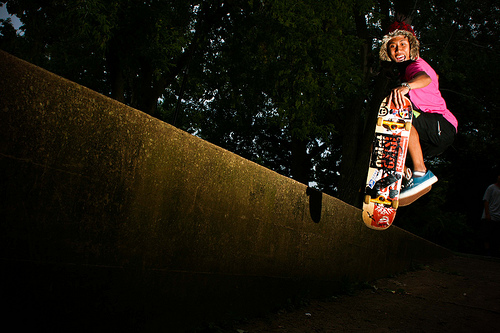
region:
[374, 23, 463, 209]
skateboarder wearing pink shirt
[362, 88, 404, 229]
decorated bottom of the skateboard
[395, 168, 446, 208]
skateboarder's blue shoes with white laces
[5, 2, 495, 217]
trees behind skateboarder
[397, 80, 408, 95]
skateboarder's wrist watch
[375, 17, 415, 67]
skateboarder's red hat with fuzzy trim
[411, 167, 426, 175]
skateboarder's white ankle sock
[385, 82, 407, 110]
skateboarder's hand gripping skateboard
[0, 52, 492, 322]
cement wall behind skateboarder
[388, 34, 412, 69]
skateboarder's smiling face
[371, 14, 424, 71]
Skateboarder is wearing a fake fur lined hat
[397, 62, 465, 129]
Skateboarder is wearing a pink t-shirt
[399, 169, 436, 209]
Girl is wearing teal and white tennis shoes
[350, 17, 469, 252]
Skateboarder is performing a trick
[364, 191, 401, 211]
The wheels on the skateboard are yellow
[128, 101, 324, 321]
Gray concrete wall to skate off of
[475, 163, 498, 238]
There is someone watching the girl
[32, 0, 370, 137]
The big green trees are blocking the sun light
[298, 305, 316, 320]
Piece of white trash is on the ground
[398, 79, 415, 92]
Skateboarder has a silver colored watch on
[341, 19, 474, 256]
A man is skateboarding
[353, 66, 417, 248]
The board has stickers on the bottom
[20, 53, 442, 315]
The edge of the ramp is grey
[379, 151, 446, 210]
Man is wearing blue and white shoes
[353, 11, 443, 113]
Man is wearing a fur hat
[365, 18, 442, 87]
The hat is brown and red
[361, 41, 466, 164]
Man is wearing a pink shirt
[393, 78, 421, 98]
Man is wearing a silver watch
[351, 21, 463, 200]
Man is wearing black shorts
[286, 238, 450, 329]
Leaves on the ground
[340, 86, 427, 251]
a skateboard with four wheels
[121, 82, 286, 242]
a concrete ledge at the skatepark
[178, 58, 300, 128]
sky peeking through the trees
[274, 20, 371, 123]
dark green tree leaves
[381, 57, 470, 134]
a pink tee shirt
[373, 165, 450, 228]
blue shoes on a boy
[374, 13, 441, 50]
a red helmet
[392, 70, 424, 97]
a watch on the boys wrist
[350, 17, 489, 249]
a boy doing a trick on a skateboard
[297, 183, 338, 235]
shadow on the wall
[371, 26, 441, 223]
Woman doing a trick on a skateboard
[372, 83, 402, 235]
Bright patterned skateboard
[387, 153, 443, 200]
Blue and white canvas shoes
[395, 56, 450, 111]
Short sleeved pink t-shirt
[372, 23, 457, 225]
Girl wearing a red fur hat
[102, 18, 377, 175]
Dark green tree cover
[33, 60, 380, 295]
Concrete skate ramp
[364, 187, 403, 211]
Brown wheels of a skateboard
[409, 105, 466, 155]
Black shorts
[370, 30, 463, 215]
Woman wearing a silver watch